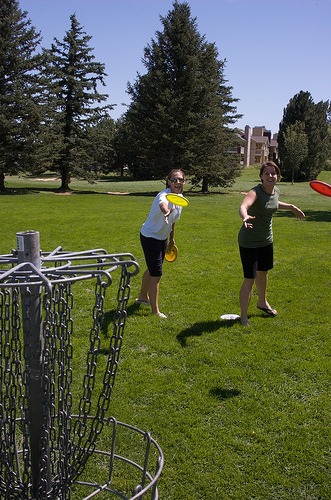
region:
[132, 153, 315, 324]
two women throwing frisbees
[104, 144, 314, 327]
people playing frisbee golf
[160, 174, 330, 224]
red and yellow frisbees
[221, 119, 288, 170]
houses behind the field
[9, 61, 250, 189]
large pine trees in the background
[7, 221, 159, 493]
metal chains for frisbee golf hole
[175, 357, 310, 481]
grass is green and cut short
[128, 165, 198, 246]
woman is wearing a white shirt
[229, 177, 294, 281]
woman is wearing a green shirt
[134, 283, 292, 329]
women are wearing flip flops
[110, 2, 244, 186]
Tall, dark evergreen tree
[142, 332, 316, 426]
Lush and plush green grass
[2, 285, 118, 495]
Black metal chain link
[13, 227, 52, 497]
Gray iron pole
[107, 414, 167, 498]
Dull gray metal basket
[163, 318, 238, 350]
Shadow of person on right cast on grass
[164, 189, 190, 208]
Young woman throwing a yellow frisbee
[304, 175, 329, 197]
Red frisbee flying through the air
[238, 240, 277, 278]
Young lady is wearing long, black shorts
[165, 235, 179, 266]
Woman is holding a yellow frisbee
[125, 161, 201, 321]
woman standing and smiling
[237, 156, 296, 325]
woman standing and smiling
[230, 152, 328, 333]
woman threw red frisbee in air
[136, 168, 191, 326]
woman threw yellow frisbee in air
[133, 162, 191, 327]
woman holding yellow frisbee in hand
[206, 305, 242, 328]
white frisbee laying on floor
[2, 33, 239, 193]
pine trees in background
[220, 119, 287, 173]
building in background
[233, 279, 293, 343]
woman wearing flip-flop shoes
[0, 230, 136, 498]
chains hanging from pole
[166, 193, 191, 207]
yellow disc in the air.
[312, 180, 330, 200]
red disc in the air.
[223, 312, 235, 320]
white disc on the ground.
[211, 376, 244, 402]
shadow on the ground.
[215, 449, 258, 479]
green grass on the ground.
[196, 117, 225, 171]
pine tree behind women.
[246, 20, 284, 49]
clear blue sky above.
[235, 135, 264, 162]
building behind the trees.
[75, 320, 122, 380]
hanging chains in the goal.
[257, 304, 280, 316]
sandal on woman's foot.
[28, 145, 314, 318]
kids playing frisbee in a park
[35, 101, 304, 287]
there's a lot of sunshine in the scene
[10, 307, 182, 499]
this is some type of chain machine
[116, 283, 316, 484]
the grass looks well kept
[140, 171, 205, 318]
this girl has 2 yellow frisbees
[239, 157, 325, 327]
this girl is flying a red frisbee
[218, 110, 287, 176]
this is a house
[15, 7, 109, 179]
a pine tree is in the park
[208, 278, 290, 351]
a white frisbee is on the ground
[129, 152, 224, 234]
this girl is wearing sun glasses